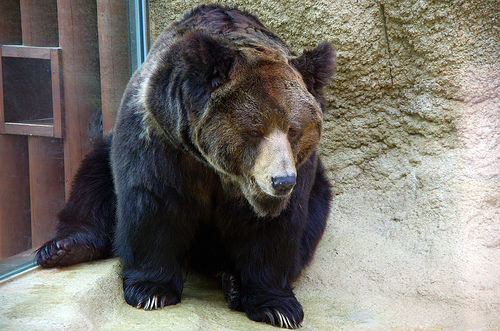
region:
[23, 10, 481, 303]
Bear sitting in the zoo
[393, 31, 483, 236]
Wall near the bear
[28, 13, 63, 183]
Wood racks near the bear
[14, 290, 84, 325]
Floor of the zoo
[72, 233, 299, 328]
Legs of the bear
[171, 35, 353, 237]
Head of the bear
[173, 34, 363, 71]
Ears of the bear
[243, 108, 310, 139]
Eyes of the bear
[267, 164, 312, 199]
Black color nose of the bear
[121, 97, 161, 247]
Black and white color hair of the bear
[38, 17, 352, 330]
The bear is sitting.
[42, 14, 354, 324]
The bear is brown.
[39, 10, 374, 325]
The bear is on the rock.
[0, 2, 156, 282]
The glass is next to the bear.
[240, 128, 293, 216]
His snout is tan.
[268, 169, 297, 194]
The nose is black.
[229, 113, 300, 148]
His eyes are brown.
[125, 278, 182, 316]
The bears claws are long.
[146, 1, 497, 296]
The rock is tan.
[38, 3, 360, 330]
The bear sitting.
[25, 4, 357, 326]
large black and brown bear with tan nose area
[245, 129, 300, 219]
tan and black muzzle area of large bear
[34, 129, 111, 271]
black back right leg of a large bear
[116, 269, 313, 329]
black front paws of a large bear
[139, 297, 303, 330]
long claws on front paws of a bear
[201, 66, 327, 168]
brown fur on the head of a large bear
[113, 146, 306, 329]
front legs of a large bear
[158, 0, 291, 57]
back of a large black bear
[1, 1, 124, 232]
red wall of a structure made of logs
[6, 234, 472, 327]
white area under and around where bear is sitting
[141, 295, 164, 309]
The claws of the bear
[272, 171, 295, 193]
The nose of the bear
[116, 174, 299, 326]
The front legs of the bear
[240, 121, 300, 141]
The eyes of the bear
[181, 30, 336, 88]
The ears of the bear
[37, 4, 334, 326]
A bear by a stone wall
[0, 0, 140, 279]
A window by the bear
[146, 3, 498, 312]
A stone wall near the window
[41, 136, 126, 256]
The back leg of the bear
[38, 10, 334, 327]
Teh bear is black and brown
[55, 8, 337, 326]
a brown bear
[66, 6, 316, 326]
a brown bear sitting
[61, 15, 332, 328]
a brown bear on stone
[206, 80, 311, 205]
a bear's round face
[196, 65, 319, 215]
a bear's brown face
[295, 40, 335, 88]
a bear's left ear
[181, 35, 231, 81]
a bear's right ear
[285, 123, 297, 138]
a bear's left eye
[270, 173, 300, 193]
a bear's black nose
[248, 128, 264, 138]
a bear's right eye